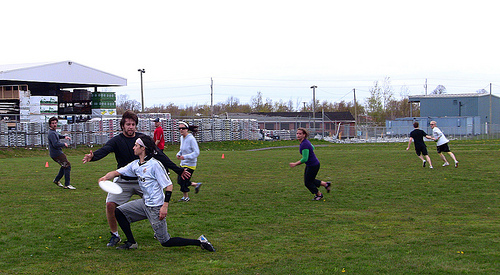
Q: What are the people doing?
A: Playing a game of Frisbee.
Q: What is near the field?
A: A large, open building.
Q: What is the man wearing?
A: Long sleeve black shirt.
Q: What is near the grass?
A: Long chain-link fence.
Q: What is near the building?
A: Stacked items.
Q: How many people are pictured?
A: 8.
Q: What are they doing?
A: Playing frisbee.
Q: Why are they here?
A: To play.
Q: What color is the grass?
A: Green.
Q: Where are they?
A: On a field.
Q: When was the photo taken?
A: During daylight hours.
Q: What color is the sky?
A: White.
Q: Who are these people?
A: Frisbee players.